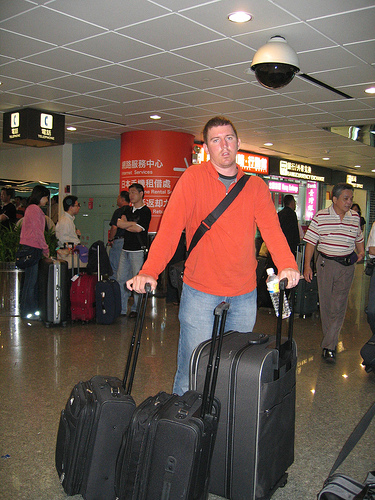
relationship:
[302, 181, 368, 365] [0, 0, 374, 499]
man in airport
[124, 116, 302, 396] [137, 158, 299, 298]
man wearing sweatshirt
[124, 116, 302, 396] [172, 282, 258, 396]
man wearing jeans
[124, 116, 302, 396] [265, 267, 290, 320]
man holding bottle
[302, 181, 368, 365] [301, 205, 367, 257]
man wearing shirt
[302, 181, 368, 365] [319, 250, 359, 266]
man wearing pouch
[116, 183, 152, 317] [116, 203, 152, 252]
man wearing shirt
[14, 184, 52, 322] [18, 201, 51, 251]
lady wearing sweater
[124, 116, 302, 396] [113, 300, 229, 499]
man with luggage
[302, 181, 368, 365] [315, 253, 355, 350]
man wearing pants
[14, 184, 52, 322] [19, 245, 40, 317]
lady wearing jeans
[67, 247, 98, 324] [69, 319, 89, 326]
suitcase on wheels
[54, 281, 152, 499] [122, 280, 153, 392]
luggage with handle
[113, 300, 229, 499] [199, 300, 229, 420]
luggage with handle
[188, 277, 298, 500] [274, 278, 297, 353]
luggage with handle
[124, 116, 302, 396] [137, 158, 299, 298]
man in sweatshirt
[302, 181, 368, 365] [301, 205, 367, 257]
man in shirt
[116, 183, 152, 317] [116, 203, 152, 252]
man in shirt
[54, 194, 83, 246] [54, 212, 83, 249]
man in shirt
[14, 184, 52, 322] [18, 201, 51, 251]
lady in shirt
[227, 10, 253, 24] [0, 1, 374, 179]
fixture in ceiling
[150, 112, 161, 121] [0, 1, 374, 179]
fixture in ceiling